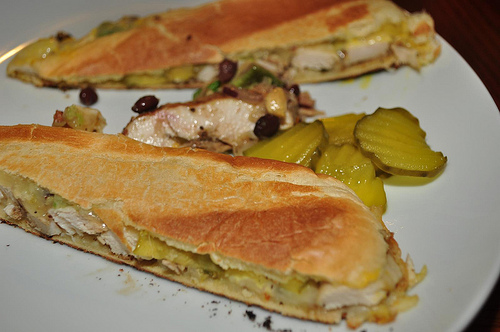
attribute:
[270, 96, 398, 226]
pickles — sliced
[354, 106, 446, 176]
pickle — green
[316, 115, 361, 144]
pickle — green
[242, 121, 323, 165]
pickle — green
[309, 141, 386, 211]
pickle — green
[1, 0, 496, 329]
plate — green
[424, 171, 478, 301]
plate — white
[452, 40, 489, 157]
plate — white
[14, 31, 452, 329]
sandwich — cut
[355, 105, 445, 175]
pickles — green